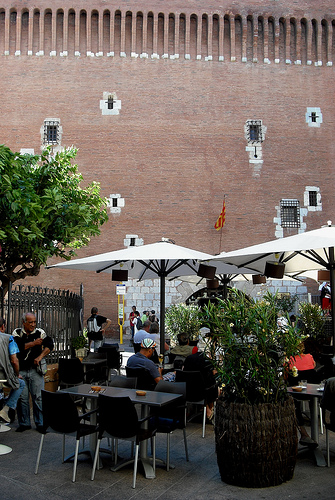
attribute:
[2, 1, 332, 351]
building — brick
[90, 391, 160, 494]
chair — black, silver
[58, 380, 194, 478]
table — black, empty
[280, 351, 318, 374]
object — orange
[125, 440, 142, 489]
leg — metal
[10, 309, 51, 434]
man — standing, older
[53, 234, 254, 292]
umbrella — white, large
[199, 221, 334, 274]
umbrella — white, large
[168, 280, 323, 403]
plant — big, green, tall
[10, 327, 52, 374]
shirt — black, white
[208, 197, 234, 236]
flas — red, yellow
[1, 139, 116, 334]
tree — small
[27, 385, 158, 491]
chairs — black, silver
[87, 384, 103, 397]
ashtray — brown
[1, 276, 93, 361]
fence — metal, grey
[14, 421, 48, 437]
shoes — black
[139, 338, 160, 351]
cap — red, white, blue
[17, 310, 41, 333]
hair — grey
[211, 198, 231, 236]
flag — red, yellow